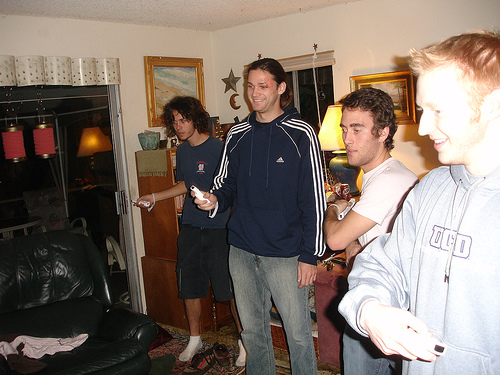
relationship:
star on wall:
[219, 69, 242, 94] [208, 1, 499, 178]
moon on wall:
[227, 93, 241, 110] [208, 1, 499, 178]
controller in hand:
[190, 184, 210, 202] [190, 189, 218, 212]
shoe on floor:
[191, 344, 225, 372] [146, 313, 343, 373]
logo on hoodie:
[276, 155, 284, 165] [209, 111, 329, 268]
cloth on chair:
[1, 328, 92, 362] [1, 228, 159, 373]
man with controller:
[190, 58, 330, 374] [190, 184, 210, 202]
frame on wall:
[142, 54, 208, 130] [208, 1, 499, 178]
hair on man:
[251, 58, 295, 110] [190, 58, 330, 374]